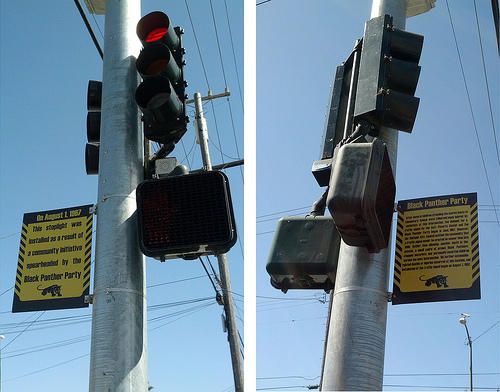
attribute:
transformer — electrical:
[188, 89, 220, 151]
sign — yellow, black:
[10, 204, 92, 312]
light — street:
[116, 11, 216, 163]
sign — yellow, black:
[17, 206, 94, 326]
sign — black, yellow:
[392, 191, 488, 309]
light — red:
[119, 16, 229, 168]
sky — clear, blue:
[1, 0, 498, 390]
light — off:
[135, 164, 234, 261]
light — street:
[124, 3, 199, 144]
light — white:
[457, 313, 469, 325]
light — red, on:
[129, 8, 191, 150]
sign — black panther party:
[391, 194, 487, 301]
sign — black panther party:
[8, 195, 94, 310]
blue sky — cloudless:
[1, 1, 492, 390]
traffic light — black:
[134, 10, 185, 137]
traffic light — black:
[355, 15, 423, 134]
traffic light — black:
[87, 80, 102, 175]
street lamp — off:
[458, 310, 475, 390]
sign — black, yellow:
[386, 190, 483, 307]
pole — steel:
[85, 10, 155, 390]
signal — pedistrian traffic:
[135, 167, 235, 259]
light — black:
[130, 8, 167, 44]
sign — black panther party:
[386, 183, 481, 311]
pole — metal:
[299, 2, 452, 389]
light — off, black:
[137, 11, 188, 139]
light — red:
[142, 22, 169, 42]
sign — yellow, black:
[394, 190, 484, 305]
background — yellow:
[400, 206, 474, 290]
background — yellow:
[17, 217, 86, 305]